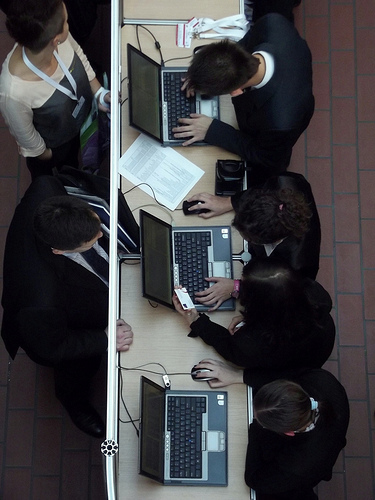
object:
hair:
[253, 375, 316, 435]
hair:
[235, 259, 304, 324]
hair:
[187, 37, 261, 98]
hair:
[46, 193, 100, 254]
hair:
[1, 4, 66, 56]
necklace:
[21, 47, 85, 118]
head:
[186, 40, 255, 100]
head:
[232, 184, 285, 246]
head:
[241, 264, 299, 336]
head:
[254, 378, 311, 435]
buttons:
[181, 408, 185, 415]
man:
[189, 358, 349, 496]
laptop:
[137, 205, 236, 315]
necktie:
[82, 248, 108, 283]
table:
[108, 0, 252, 499]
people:
[0, 0, 110, 195]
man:
[1, 180, 131, 436]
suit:
[1, 181, 110, 371]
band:
[22, 44, 79, 103]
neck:
[16, 34, 54, 67]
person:
[186, 169, 321, 315]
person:
[172, 267, 337, 371]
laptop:
[124, 40, 220, 148]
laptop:
[137, 374, 229, 488]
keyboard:
[162, 72, 199, 146]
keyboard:
[174, 229, 213, 301]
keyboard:
[165, 395, 208, 475]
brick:
[330, 94, 357, 149]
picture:
[0, 1, 373, 499]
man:
[170, 12, 315, 168]